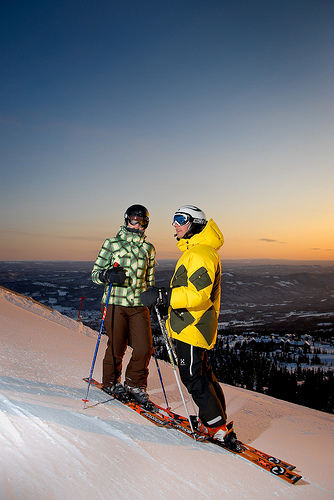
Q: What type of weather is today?
A: It is clear.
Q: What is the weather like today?
A: It is clear.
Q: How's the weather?
A: It is clear.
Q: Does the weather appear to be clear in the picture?
A: Yes, it is clear.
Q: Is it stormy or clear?
A: It is clear.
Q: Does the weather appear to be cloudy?
A: No, it is clear.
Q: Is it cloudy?
A: No, it is clear.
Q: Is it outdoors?
A: Yes, it is outdoors.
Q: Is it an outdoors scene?
A: Yes, it is outdoors.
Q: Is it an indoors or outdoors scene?
A: It is outdoors.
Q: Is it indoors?
A: No, it is outdoors.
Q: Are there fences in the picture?
A: No, there are no fences.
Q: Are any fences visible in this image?
A: No, there are no fences.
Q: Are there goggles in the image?
A: Yes, there are goggles.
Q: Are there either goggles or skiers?
A: Yes, there are goggles.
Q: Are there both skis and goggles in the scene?
A: Yes, there are both goggles and a ski.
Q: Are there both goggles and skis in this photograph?
A: Yes, there are both goggles and a ski.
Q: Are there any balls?
A: No, there are no balls.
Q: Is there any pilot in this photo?
A: No, there are no pilots.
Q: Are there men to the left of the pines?
A: Yes, there is a man to the left of the pines.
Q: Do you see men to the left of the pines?
A: Yes, there is a man to the left of the pines.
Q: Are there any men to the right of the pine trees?
A: No, the man is to the left of the pine trees.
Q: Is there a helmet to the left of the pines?
A: No, there is a man to the left of the pines.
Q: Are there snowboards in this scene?
A: No, there are no snowboards.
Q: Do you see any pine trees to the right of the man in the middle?
A: Yes, there are pine trees to the right of the man.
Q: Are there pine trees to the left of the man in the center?
A: No, the pine trees are to the right of the man.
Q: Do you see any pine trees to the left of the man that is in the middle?
A: No, the pine trees are to the right of the man.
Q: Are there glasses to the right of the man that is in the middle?
A: No, there are pine trees to the right of the man.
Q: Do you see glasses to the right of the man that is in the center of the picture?
A: No, there are pine trees to the right of the man.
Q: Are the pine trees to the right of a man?
A: Yes, the pine trees are to the right of a man.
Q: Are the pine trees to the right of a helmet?
A: No, the pine trees are to the right of a man.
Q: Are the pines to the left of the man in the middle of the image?
A: No, the pines are to the right of the man.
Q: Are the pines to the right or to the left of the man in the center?
A: The pines are to the right of the man.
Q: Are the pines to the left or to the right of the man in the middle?
A: The pines are to the right of the man.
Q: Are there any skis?
A: Yes, there are skis.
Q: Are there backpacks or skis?
A: Yes, there are skis.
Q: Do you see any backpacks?
A: No, there are no backpacks.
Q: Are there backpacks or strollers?
A: No, there are no backpacks or strollers.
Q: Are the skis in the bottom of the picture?
A: Yes, the skis are in the bottom of the image.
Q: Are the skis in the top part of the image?
A: No, the skis are in the bottom of the image.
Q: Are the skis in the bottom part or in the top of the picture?
A: The skis are in the bottom of the image.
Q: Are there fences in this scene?
A: No, there are no fences.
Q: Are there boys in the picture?
A: No, there are no boys.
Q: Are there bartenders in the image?
A: No, there are no bartenders.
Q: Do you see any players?
A: No, there are no players.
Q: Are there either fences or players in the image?
A: No, there are no players or fences.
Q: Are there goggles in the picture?
A: Yes, there are goggles.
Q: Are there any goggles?
A: Yes, there are goggles.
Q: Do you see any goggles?
A: Yes, there are goggles.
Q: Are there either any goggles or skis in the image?
A: Yes, there are goggles.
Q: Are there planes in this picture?
A: No, there are no planes.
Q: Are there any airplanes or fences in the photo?
A: No, there are no airplanes or fences.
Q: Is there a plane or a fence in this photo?
A: No, there are no airplanes or fences.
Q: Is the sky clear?
A: Yes, the sky is clear.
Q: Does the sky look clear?
A: Yes, the sky is clear.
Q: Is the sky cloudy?
A: No, the sky is clear.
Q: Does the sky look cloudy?
A: No, the sky is clear.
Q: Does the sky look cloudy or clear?
A: The sky is clear.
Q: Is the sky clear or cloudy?
A: The sky is clear.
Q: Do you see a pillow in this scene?
A: No, there are no pillows.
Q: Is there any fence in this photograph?
A: No, there are no fences.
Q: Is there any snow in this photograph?
A: Yes, there is snow.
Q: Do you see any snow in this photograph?
A: Yes, there is snow.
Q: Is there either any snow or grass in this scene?
A: Yes, there is snow.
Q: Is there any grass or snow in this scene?
A: Yes, there is snow.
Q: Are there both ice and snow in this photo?
A: No, there is snow but no ice.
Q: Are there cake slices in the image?
A: No, there are no cake slices.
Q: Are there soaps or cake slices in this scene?
A: No, there are no cake slices or soaps.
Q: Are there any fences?
A: No, there are no fences.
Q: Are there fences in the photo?
A: No, there are no fences.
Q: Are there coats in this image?
A: Yes, there is a coat.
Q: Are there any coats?
A: Yes, there is a coat.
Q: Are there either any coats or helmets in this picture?
A: Yes, there is a coat.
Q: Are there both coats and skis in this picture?
A: Yes, there are both a coat and skis.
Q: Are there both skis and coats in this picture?
A: Yes, there are both a coat and skis.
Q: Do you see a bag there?
A: No, there are no bags.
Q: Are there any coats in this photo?
A: Yes, there is a coat.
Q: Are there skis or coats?
A: Yes, there is a coat.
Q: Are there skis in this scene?
A: Yes, there are skis.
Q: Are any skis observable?
A: Yes, there are skis.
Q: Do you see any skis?
A: Yes, there are skis.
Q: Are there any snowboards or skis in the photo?
A: Yes, there are skis.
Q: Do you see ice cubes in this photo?
A: No, there are no ice cubes.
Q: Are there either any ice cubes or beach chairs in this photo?
A: No, there are no ice cubes or beach chairs.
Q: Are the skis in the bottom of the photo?
A: Yes, the skis are in the bottom of the image.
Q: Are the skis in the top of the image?
A: No, the skis are in the bottom of the image.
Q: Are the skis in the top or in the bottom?
A: The skis are in the bottom of the image.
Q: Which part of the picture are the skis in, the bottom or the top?
A: The skis are in the bottom of the image.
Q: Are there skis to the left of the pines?
A: Yes, there are skis to the left of the pines.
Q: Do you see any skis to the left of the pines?
A: Yes, there are skis to the left of the pines.